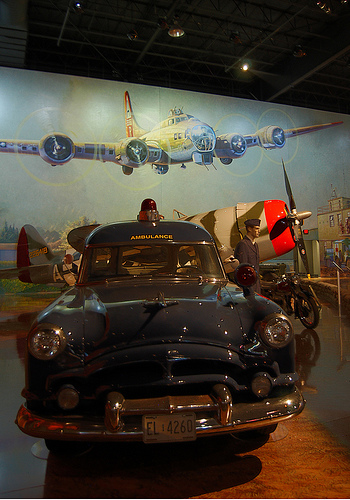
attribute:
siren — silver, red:
[126, 196, 168, 225]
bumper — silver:
[12, 381, 315, 444]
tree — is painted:
[0, 224, 19, 242]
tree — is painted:
[49, 224, 73, 247]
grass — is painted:
[3, 282, 57, 308]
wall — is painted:
[4, 68, 340, 258]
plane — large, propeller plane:
[8, 80, 346, 173]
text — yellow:
[129, 234, 173, 239]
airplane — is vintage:
[4, 158, 313, 294]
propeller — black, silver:
[279, 162, 313, 275]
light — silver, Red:
[128, 188, 168, 217]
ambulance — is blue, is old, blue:
[15, 197, 306, 452]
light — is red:
[134, 194, 164, 224]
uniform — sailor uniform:
[230, 232, 265, 288]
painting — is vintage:
[0, 65, 348, 292]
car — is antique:
[19, 200, 320, 477]